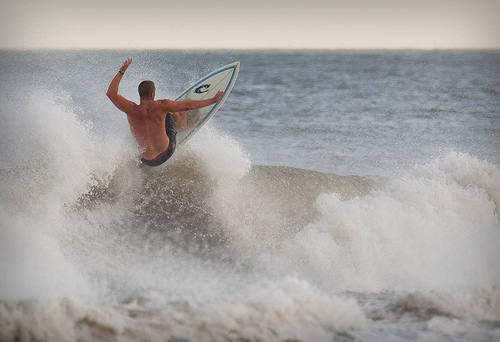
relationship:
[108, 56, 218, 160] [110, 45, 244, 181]
man on surfboard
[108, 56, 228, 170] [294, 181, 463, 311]
man surfing wave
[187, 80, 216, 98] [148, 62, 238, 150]
design on surfboard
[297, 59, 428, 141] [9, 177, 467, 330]
ripples in water